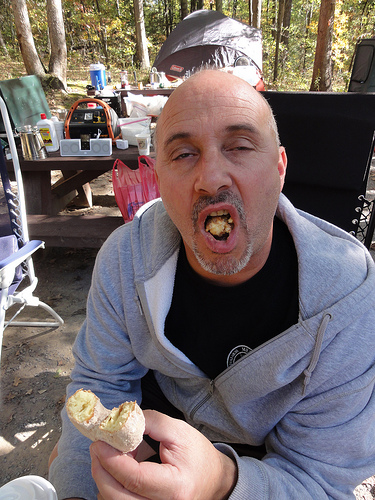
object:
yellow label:
[38, 128, 53, 147]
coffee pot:
[27, 126, 48, 160]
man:
[48, 68, 374, 500]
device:
[59, 98, 121, 150]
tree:
[9, 0, 68, 79]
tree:
[131, 0, 150, 67]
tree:
[272, 0, 286, 85]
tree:
[310, 0, 335, 94]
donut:
[205, 217, 232, 236]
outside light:
[20, 1, 37, 56]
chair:
[0, 93, 63, 355]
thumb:
[142, 407, 184, 445]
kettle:
[19, 123, 33, 158]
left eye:
[224, 143, 256, 153]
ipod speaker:
[59, 138, 113, 157]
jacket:
[48, 193, 372, 500]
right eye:
[171, 146, 200, 163]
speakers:
[59, 137, 82, 157]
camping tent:
[150, 8, 264, 84]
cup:
[135, 134, 151, 157]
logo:
[226, 345, 253, 368]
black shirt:
[164, 208, 300, 379]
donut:
[65, 386, 146, 456]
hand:
[88, 409, 227, 499]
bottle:
[36, 112, 59, 152]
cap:
[40, 113, 46, 120]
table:
[0, 91, 166, 219]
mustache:
[189, 191, 253, 278]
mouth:
[196, 201, 239, 254]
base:
[0, 260, 63, 356]